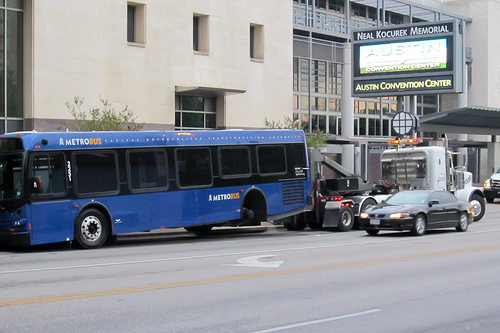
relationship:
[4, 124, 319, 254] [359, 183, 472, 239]
bus beside car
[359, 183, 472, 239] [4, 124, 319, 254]
car beside bus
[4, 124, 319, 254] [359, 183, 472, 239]
bus close to car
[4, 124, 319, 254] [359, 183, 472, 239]
bus near car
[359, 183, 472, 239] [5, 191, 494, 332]
car on road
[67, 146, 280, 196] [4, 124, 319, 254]
windows on bus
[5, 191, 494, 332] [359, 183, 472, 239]
road below car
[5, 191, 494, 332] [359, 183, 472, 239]
road under car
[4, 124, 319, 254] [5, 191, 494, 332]
bus above road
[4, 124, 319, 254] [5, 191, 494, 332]
bus on road